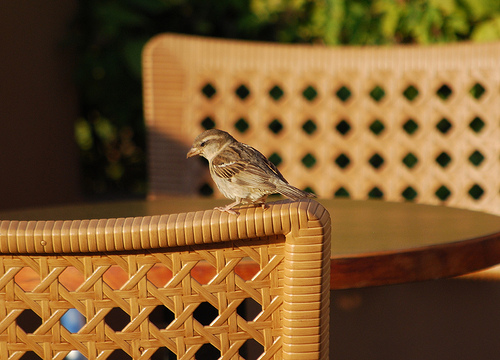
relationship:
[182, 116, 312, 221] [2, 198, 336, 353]
bird sits on chair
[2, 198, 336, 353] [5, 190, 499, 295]
chair next to table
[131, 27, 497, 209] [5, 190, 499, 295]
chair next to table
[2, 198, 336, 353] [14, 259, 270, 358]
chair has holes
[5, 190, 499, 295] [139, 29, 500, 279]
table between chair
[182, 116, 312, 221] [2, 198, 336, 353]
bird on chair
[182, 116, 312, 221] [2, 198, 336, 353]
bird perched on chair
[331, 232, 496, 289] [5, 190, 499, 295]
edge of table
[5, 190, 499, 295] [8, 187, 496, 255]
table has surface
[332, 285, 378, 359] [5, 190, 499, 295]
leg of table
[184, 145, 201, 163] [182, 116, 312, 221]
beak of bird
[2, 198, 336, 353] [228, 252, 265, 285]
chair has hole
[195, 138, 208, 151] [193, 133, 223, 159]
eye on left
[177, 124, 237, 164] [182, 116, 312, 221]
head of bird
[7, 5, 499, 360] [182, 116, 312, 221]
picture showing wildlife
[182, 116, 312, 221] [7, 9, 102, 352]
bird facing left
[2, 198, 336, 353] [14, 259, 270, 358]
chair has wicker back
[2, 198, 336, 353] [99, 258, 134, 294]
chair diamond spaces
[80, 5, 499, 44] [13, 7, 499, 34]
vegetation on back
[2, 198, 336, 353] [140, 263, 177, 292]
chair hole design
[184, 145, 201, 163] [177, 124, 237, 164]
beak on head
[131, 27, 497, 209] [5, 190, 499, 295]
chair behind table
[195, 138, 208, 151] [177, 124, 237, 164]
eye on head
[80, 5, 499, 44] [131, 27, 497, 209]
vegetation behind chair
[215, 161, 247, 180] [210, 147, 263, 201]
wing on side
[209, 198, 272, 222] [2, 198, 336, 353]
feet on chair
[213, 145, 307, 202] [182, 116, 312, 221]
feathers on bird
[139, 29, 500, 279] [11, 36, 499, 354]
chair on patio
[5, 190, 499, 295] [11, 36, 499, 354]
table on patio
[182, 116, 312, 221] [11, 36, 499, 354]
bird on furniture